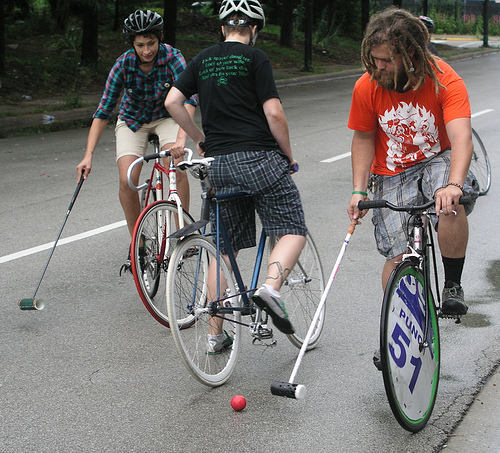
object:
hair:
[357, 6, 448, 102]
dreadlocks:
[384, 40, 399, 91]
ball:
[227, 393, 247, 413]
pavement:
[0, 53, 499, 453]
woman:
[75, 5, 197, 278]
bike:
[163, 141, 329, 387]